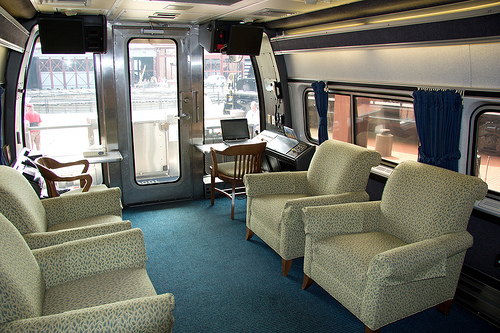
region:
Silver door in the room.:
[113, 28, 208, 199]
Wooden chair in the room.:
[207, 145, 277, 192]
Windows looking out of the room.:
[356, 99, 423, 172]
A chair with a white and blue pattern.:
[379, 173, 466, 312]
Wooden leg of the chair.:
[299, 265, 316, 298]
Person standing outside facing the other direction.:
[21, 100, 61, 152]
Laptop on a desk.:
[218, 113, 266, 150]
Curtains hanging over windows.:
[311, 85, 333, 137]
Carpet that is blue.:
[166, 226, 245, 316]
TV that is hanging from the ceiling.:
[35, 11, 114, 61]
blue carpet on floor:
[105, 189, 495, 331]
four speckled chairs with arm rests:
[3, 140, 485, 332]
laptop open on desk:
[218, 119, 251, 147]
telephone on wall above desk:
[270, 78, 283, 128]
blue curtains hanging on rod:
[282, 75, 467, 176]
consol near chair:
[252, 128, 308, 159]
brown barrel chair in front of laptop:
[207, 140, 263, 220]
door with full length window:
[111, 22, 197, 202]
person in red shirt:
[22, 108, 38, 123]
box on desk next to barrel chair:
[24, 145, 124, 195]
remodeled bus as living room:
[1, 0, 498, 332]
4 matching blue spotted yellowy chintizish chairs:
[1, 134, 491, 331]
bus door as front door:
[115, 26, 197, 207]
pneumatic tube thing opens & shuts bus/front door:
[126, 26, 173, 36]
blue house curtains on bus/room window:
[308, 79, 465, 171]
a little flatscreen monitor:
[216, 115, 252, 145]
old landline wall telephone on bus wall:
[269, 76, 285, 132]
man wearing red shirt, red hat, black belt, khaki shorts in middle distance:
[21, 100, 46, 155]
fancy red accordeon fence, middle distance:
[32, 57, 99, 95]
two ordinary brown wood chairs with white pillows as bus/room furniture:
[33, 139, 271, 229]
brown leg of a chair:
[237, 220, 261, 248]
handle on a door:
[171, 109, 193, 124]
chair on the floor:
[296, 150, 496, 330]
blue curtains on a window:
[302, 75, 332, 150]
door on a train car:
[104, 14, 212, 219]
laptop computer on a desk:
[215, 114, 259, 151]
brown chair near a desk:
[198, 137, 270, 224]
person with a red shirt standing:
[16, 97, 49, 150]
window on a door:
[118, 32, 188, 192]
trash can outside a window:
[368, 122, 398, 164]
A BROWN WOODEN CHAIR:
[205, 136, 274, 222]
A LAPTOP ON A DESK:
[213, 113, 260, 147]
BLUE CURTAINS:
[402, 83, 482, 176]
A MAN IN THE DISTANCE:
[11, 98, 63, 153]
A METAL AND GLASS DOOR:
[93, 21, 209, 204]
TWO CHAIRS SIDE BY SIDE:
[241, 130, 492, 332]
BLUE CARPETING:
[141, 208, 300, 329]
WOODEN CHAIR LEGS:
[236, 221, 298, 286]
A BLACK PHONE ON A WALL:
[260, 71, 298, 138]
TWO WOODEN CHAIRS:
[30, 136, 275, 223]